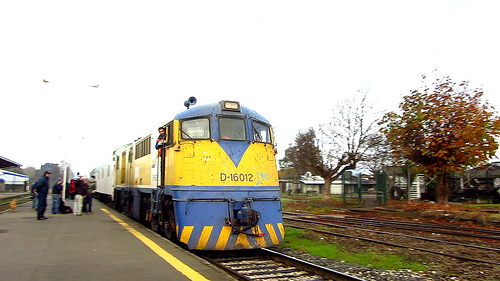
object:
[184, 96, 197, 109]
horn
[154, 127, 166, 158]
man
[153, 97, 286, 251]
engine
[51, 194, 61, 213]
pants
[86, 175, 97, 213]
man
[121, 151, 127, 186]
door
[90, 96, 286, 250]
car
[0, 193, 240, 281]
platform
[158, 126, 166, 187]
door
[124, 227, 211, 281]
line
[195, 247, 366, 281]
railroad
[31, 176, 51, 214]
clothes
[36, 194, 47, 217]
pants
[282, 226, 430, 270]
grass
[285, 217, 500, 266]
railroad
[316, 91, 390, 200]
tree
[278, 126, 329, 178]
leaves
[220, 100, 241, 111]
light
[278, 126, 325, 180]
trees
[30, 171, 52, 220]
man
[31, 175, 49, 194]
jacket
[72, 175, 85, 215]
man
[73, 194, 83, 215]
pants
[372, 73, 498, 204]
tree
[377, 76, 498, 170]
leaves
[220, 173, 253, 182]
d-16012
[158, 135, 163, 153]
vest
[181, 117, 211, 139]
engine window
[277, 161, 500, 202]
houses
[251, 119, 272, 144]
train window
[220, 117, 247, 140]
train window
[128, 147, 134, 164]
train window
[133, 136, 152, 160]
train window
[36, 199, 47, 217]
person's leg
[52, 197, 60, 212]
person's leg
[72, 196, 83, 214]
person's leg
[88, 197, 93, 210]
person's leg